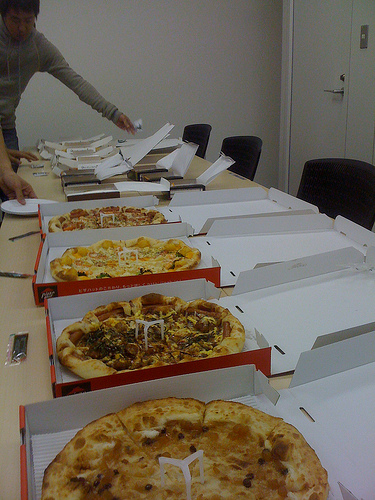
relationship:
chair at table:
[180, 122, 214, 162] [1, 136, 373, 499]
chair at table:
[219, 133, 265, 182] [1, 136, 373, 499]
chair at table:
[298, 159, 374, 231] [1, 136, 373, 499]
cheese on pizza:
[118, 447, 197, 484] [42, 400, 283, 465]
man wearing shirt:
[0, 0, 139, 222] [2, 35, 118, 131]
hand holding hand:
[0, 145, 41, 169] [0, 135, 43, 206]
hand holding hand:
[0, 145, 41, 169] [107, 108, 139, 136]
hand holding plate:
[0, 145, 41, 169] [0, 192, 67, 217]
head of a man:
[0, 0, 48, 42] [0, 0, 140, 161]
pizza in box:
[47, 206, 169, 231] [32, 207, 374, 306]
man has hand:
[0, 129, 40, 204] [3, 176, 39, 204]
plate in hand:
[0, 192, 67, 217] [3, 176, 39, 204]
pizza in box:
[47, 206, 169, 231] [39, 182, 318, 240]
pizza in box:
[50, 236, 198, 279] [32, 207, 374, 306]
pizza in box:
[56, 290, 242, 375] [46, 245, 373, 400]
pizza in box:
[42, 396, 328, 498] [18, 328, 373, 494]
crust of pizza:
[206, 398, 279, 433] [42, 396, 328, 498]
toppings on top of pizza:
[112, 322, 177, 357] [68, 291, 239, 365]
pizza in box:
[42, 396, 328, 498] [22, 393, 355, 495]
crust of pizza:
[66, 347, 91, 376] [56, 290, 242, 375]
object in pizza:
[114, 245, 138, 263] [50, 236, 198, 279]